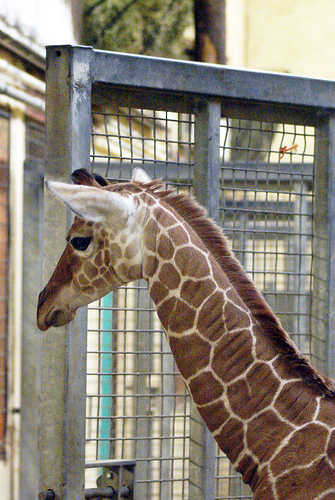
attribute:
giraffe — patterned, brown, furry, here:
[36, 167, 324, 500]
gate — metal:
[39, 44, 333, 499]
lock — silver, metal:
[40, 448, 134, 498]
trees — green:
[83, 1, 210, 75]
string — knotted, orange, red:
[277, 139, 299, 159]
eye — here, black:
[68, 230, 100, 251]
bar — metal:
[192, 93, 219, 499]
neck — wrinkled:
[147, 177, 334, 495]